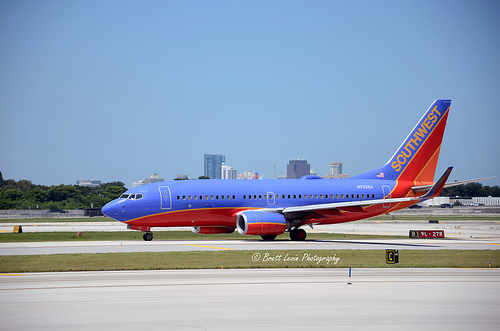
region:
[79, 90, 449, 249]
red blue and orange passenger jet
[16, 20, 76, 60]
white clouds in blue sky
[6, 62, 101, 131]
white clouds in blue sky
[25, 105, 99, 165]
white clouds in blue sky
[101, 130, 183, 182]
white clouds in blue sky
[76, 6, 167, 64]
white clouds in blue sky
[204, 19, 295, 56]
white clouds in blue sky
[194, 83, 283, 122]
white clouds in blue sky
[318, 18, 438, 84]
white clouds in blue sky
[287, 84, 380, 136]
white clouds in blue sky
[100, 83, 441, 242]
multi colored passenger plane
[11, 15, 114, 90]
white clouds in blue sky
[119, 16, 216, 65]
white clouds in blue sky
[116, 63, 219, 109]
white clouds in blue sky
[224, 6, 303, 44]
white clouds in blue sky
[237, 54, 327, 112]
white clouds in blue sky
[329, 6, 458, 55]
white clouds in blue sky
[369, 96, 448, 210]
tail of plane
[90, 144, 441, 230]
Southwest airlines plane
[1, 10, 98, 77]
white clouds on blue sky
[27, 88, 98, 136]
white clouds on blue sky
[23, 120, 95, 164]
white clouds on blue sky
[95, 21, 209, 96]
white clouds on blue sky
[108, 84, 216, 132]
white clouds on blue sky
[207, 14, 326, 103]
white clouds on blue sky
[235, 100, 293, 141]
white clouds on blue sky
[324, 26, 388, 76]
white clouds on blue sky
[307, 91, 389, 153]
white clouds on blue sky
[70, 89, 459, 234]
blue and orange passenger jet on run way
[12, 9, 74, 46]
white clouds in blue sky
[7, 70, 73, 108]
white clouds in blue sky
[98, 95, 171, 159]
white clouds in blue sky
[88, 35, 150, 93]
white clouds in blue sky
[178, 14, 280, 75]
white clouds in blue sky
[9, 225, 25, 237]
a yellow sign on ground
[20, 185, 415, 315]
a few plane runways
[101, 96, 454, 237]
a blue and red plane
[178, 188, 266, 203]
a row of small windows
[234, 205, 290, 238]
a large plane engine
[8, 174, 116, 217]
a variety of trees in the background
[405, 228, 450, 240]
a large red sign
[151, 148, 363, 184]
a city in the background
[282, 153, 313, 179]
a tall brown building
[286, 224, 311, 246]
some plane landing gear